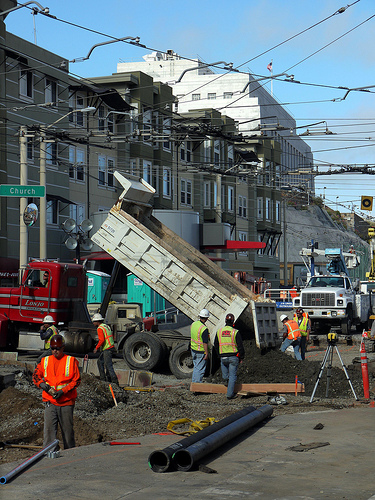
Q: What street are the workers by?
A: Church St.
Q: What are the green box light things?
A: Porta-potties.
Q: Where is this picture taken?
A: A construction site.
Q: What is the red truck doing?
A: Dumping material.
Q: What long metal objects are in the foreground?
A: Pipes.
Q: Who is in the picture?
A: Seven men.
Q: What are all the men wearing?
A: Safety vests.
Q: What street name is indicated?
A: Church.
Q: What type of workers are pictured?
A: Construction workers.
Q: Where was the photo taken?
A: On a city street.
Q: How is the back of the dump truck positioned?
A: At an incline.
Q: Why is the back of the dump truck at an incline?
A: To dump its load.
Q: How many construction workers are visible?
A: Seven.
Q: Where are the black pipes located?
A: To the right of the hole in the street.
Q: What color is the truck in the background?
A: White.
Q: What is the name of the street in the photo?
A: Church.